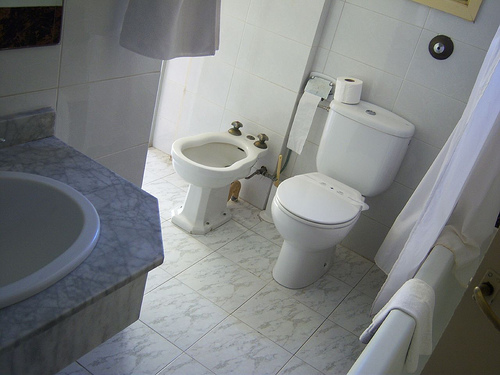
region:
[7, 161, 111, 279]
a white sink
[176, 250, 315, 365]
white tile on the floor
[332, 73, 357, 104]
a roll of toilet paper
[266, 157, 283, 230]
a toilet brush on the floor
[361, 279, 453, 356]
a white towel on the bath tub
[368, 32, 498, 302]
a white shower curtain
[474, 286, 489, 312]
a handle on the door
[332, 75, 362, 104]
a roll of white toilet tissue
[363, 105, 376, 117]
the flush on top of the tank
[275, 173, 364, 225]
the lid to the toilet seat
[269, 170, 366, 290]
a toilet bowl with seat and lid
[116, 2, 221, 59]
a white towel on the wall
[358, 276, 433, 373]
a white mat on the side of the tub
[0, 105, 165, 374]
a sink in the bathroom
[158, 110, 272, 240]
a white bidet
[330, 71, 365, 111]
a roll of toilet paper on the back of a toilet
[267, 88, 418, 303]
a white toilet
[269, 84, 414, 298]
a toilet with a closed lid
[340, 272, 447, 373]
a towel over the side of a bathtub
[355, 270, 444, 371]
a small white towel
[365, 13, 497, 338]
a white shower curtain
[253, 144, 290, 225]
a toilet bowl brush with a yellow handle in a white container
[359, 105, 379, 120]
a silver push button toilet flush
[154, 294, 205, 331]
white tile on floor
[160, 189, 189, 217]
white tile on floor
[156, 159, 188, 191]
white tile on floor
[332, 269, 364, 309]
white tile on floor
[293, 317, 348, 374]
white tile on floor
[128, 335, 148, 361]
white tile on floor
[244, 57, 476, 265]
a bathroom toilet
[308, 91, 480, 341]
a toilet that is in the bathroom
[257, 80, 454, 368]
a bathroom toilet that is white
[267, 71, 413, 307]
a white bathroom toilet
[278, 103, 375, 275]
toilet with lid down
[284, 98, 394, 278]
toilet with seat down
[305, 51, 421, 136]
a roll of toilet paper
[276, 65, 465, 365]
a white bathroom toilet with seat down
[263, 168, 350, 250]
a toilet in the bathroom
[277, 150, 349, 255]
a toilet is white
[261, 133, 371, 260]
a bathroom toilet is white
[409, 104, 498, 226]
a white shower curtain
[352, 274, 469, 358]
a white towel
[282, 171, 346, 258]
a toilet seat down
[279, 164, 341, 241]
a lid is white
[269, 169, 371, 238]
paper seal on white toilet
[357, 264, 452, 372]
white towel hanging on bathtub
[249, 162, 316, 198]
silver pipe running to toilet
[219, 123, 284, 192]
silver pipe running to toilet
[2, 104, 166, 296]
white sink on grey marble counter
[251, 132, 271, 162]
brass knob on white toilet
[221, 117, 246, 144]
brass knob on white toilet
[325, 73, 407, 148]
toilet paper roll on tank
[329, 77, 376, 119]
white toilet paper roll on tank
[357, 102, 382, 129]
chrome button on white toilet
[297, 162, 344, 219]
toilet seat is down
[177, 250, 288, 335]
grey and white tile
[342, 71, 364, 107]
white roll on toilet